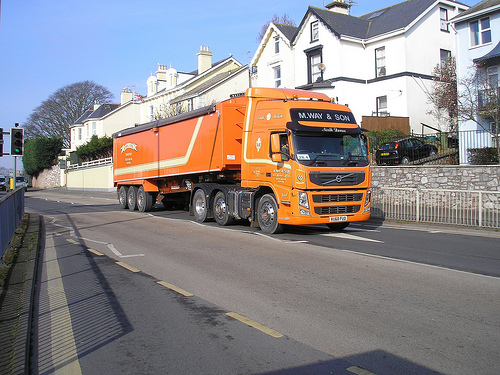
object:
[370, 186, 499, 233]
truck grill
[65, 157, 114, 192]
fence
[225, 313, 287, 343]
lines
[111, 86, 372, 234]
truck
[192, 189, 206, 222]
tire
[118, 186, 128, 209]
tire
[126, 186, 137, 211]
tire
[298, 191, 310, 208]
headlights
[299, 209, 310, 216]
light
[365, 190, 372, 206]
light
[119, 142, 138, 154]
sign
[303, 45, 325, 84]
trim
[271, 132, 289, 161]
mirror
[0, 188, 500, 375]
road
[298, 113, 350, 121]
letters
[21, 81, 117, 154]
trees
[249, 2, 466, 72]
roof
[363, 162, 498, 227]
wall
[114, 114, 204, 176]
line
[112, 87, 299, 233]
side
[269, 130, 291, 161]
window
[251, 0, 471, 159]
house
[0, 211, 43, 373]
road edge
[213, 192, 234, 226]
tire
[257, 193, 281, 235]
tire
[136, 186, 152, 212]
tire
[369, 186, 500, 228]
fence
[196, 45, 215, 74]
chimney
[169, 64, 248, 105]
rooftop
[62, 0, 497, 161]
homes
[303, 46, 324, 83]
window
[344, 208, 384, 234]
shadow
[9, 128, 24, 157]
streetlight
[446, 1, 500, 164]
house